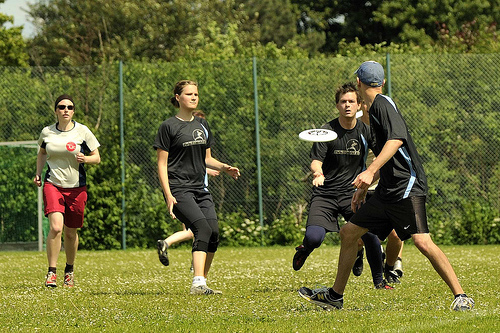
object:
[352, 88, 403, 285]
man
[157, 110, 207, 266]
man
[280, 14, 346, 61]
mid air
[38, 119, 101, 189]
shirt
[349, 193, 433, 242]
shorts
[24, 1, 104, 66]
trees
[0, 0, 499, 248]
bushes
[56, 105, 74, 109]
sunglasses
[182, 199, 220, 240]
knee bands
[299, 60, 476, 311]
guy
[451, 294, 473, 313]
sneakers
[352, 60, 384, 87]
cap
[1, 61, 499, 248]
fence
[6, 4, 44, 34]
sky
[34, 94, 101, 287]
female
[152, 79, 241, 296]
female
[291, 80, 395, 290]
male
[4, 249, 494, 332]
grass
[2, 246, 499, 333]
flowers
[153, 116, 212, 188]
shirt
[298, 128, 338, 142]
frisbee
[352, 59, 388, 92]
head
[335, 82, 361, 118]
head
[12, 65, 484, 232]
fence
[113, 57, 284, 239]
poles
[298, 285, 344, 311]
shoes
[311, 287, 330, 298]
laces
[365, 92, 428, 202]
shirt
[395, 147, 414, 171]
stripe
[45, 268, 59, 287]
sneakers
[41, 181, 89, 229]
shorts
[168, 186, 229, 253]
leggings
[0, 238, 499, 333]
field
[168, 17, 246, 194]
tree